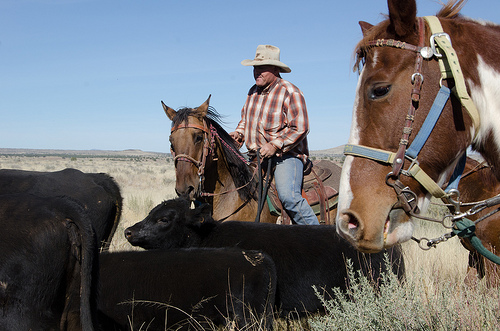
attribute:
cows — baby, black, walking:
[138, 191, 280, 329]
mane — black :
[163, 102, 243, 152]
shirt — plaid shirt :
[231, 77, 321, 167]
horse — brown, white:
[335, 0, 498, 286]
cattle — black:
[2, 167, 394, 327]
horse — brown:
[152, 90, 359, 230]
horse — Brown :
[156, 93, 338, 225]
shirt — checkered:
[233, 85, 314, 158]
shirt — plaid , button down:
[235, 76, 313, 172]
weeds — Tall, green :
[306, 251, 493, 326]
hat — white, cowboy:
[222, 40, 337, 87]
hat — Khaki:
[223, 29, 308, 82]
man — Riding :
[233, 45, 321, 227]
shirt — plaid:
[232, 81, 308, 160]